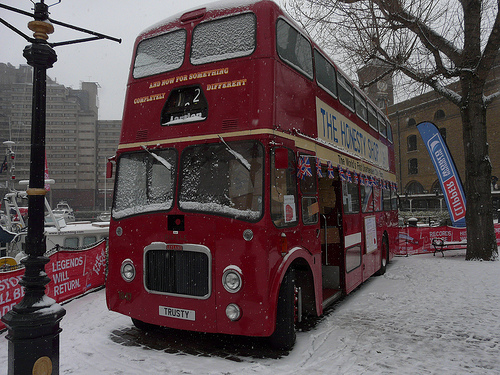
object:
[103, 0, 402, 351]
bus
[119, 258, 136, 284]
lights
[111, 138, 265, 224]
windshield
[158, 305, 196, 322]
sign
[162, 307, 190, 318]
trusty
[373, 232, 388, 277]
tires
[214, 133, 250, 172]
wipers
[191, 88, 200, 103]
2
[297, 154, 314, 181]
flags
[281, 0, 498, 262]
tree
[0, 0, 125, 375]
post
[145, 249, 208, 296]
grill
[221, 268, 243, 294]
headlight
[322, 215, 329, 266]
bar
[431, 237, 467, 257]
bench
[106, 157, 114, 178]
mirror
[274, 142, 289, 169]
mirror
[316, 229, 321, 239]
handle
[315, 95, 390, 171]
sign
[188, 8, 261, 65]
windows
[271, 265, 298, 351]
tire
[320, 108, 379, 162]
honesty shop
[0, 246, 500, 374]
snow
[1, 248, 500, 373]
ground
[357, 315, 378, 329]
footprints